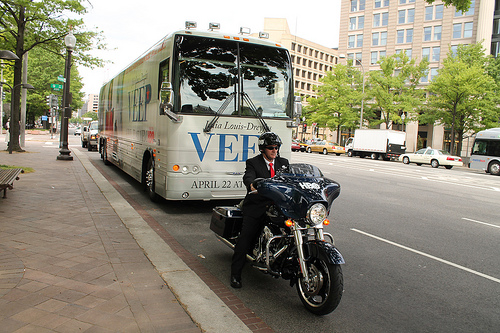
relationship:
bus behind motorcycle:
[97, 20, 303, 204] [209, 132, 345, 317]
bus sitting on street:
[97, 20, 303, 204] [74, 128, 498, 329]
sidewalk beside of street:
[2, 130, 203, 332] [74, 128, 498, 329]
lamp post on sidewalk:
[57, 28, 80, 161] [2, 130, 203, 332]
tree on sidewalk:
[2, 1, 115, 157] [2, 130, 203, 332]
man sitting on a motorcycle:
[230, 131, 291, 289] [209, 132, 345, 317]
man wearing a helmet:
[230, 131, 291, 289] [258, 131, 284, 154]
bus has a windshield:
[97, 20, 303, 204] [173, 33, 295, 119]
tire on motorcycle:
[296, 257, 344, 316] [209, 132, 345, 317]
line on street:
[348, 228, 500, 284] [74, 128, 498, 329]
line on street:
[458, 214, 497, 226] [74, 128, 498, 329]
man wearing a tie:
[230, 131, 291, 289] [266, 159, 276, 178]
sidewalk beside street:
[2, 130, 203, 332] [74, 128, 498, 329]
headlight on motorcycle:
[305, 203, 329, 224] [209, 132, 345, 317]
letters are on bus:
[187, 131, 261, 167] [97, 20, 303, 204]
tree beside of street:
[2, 1, 115, 157] [74, 128, 498, 329]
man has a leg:
[230, 131, 291, 289] [225, 210, 267, 289]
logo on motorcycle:
[296, 180, 325, 192] [209, 132, 345, 317]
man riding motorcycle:
[230, 131, 291, 289] [209, 132, 345, 317]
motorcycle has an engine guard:
[209, 132, 345, 317] [263, 232, 286, 273]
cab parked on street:
[400, 142, 463, 171] [74, 128, 498, 329]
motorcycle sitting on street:
[209, 132, 345, 317] [74, 128, 498, 329]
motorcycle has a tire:
[209, 132, 345, 317] [296, 257, 344, 316]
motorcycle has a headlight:
[209, 132, 345, 317] [305, 203, 329, 224]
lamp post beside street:
[57, 28, 80, 161] [74, 128, 498, 329]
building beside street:
[330, 1, 496, 160] [74, 128, 498, 329]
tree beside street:
[2, 1, 115, 157] [74, 128, 498, 329]